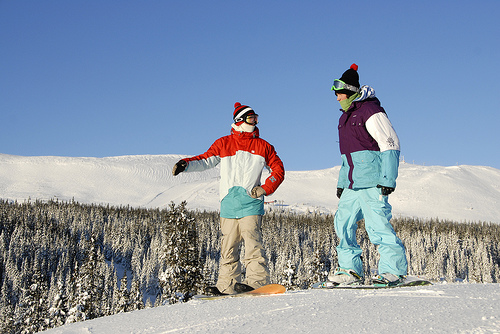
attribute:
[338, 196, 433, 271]
pants — blue 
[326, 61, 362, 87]
hat — black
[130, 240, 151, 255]
snow — white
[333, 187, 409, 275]
trousers — blue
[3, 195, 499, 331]
trees — Bunch of green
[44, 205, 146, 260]
trees — Bunch of green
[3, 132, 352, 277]
mountain top — sunny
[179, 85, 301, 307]
man — pictured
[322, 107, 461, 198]
jacket — warm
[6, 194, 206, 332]
trees — green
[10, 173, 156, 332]
trees — Bunch of green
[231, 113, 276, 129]
goggles — ski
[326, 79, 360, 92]
goggles — ski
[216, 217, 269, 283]
trousers — pictured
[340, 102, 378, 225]
outfit — purple and white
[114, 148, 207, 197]
ball — red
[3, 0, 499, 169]
sky — pictured